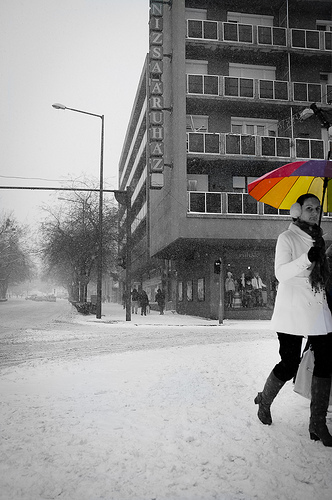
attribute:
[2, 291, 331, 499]
street — snowy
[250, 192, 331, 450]
woman — walking, young, light skinned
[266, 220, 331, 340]
coat — white, light colored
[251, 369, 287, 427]
boot — black, dark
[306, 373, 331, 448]
boot — black, dark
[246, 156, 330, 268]
umbrella — colorful, rainbow colored, colored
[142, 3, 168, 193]
sign — vertical, black, white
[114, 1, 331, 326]
building — tall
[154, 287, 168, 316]
person — walking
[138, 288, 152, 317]
person — walking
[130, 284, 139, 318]
person — walking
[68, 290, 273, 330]
sidewalk — snowy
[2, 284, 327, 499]
snow — lumpy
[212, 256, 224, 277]
sign — walk/don't walk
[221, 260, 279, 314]
window — black, white, street level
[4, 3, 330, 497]
scene — black, white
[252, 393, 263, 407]
heel — 1 inch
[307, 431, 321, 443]
heel — 1 inch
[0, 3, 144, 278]
sky — grey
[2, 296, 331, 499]
ground — white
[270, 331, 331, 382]
pants — dark